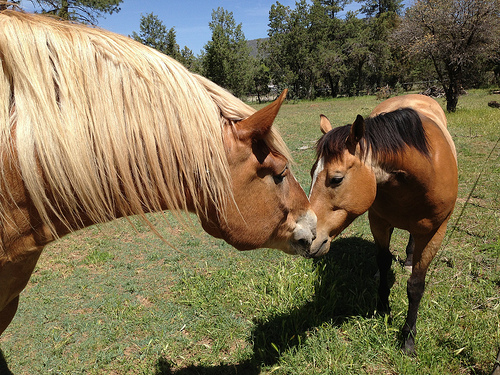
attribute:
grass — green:
[0, 85, 499, 373]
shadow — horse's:
[150, 220, 395, 370]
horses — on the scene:
[5, 9, 317, 361]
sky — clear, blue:
[2, 1, 423, 46]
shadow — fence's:
[418, 135, 498, 327]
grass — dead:
[164, 257, 282, 352]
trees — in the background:
[123, 2, 498, 87]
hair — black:
[315, 107, 433, 170]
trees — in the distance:
[262, 0, 499, 97]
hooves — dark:
[374, 299, 419, 358]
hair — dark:
[308, 101, 438, 160]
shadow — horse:
[231, 236, 465, 373]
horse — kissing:
[299, 93, 458, 355]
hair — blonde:
[5, 25, 215, 245]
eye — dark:
[329, 174, 341, 184]